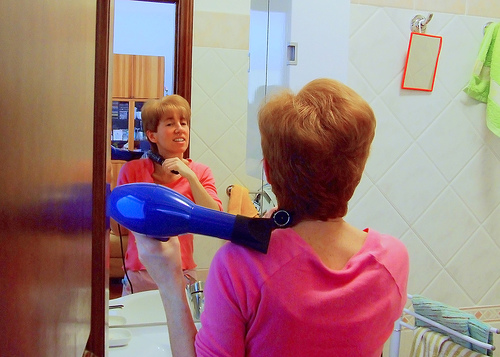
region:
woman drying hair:
[133, 82, 402, 312]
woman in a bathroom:
[184, 77, 444, 309]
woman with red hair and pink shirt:
[178, 72, 408, 342]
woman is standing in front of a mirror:
[142, 75, 339, 345]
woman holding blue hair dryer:
[106, 172, 270, 252]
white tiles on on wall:
[403, 102, 475, 269]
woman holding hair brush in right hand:
[136, 144, 188, 181]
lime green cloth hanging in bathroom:
[453, 7, 498, 142]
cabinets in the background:
[104, 37, 149, 163]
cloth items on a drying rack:
[391, 285, 496, 350]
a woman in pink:
[289, 251, 347, 348]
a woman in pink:
[313, 296, 341, 350]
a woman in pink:
[270, 204, 318, 286]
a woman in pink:
[239, 309, 293, 351]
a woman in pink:
[328, 296, 363, 352]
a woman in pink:
[269, 270, 336, 344]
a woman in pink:
[285, 259, 314, 301]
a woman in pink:
[307, 259, 344, 311]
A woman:
[273, 231, 362, 353]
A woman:
[276, 211, 326, 301]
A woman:
[286, 180, 333, 290]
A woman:
[305, 325, 322, 352]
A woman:
[294, 341, 300, 349]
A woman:
[296, 225, 334, 315]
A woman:
[302, 339, 307, 352]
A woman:
[271, 243, 310, 343]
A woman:
[299, 284, 341, 342]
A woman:
[311, 234, 353, 338]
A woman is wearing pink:
[221, 127, 357, 352]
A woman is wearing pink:
[298, 167, 356, 335]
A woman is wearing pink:
[322, 162, 372, 352]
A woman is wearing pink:
[311, 244, 340, 352]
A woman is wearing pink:
[278, 130, 338, 355]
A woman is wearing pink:
[305, 141, 338, 286]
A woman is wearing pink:
[268, 72, 317, 317]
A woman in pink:
[216, 228, 354, 348]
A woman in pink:
[285, 250, 335, 333]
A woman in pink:
[286, 250, 321, 293]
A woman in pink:
[291, 248, 378, 355]